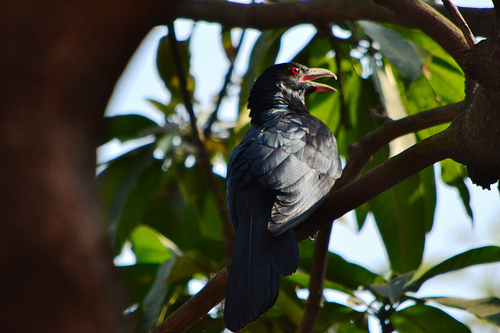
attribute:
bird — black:
[206, 50, 388, 287]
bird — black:
[194, 38, 394, 294]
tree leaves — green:
[403, 245, 499, 290]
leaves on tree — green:
[354, 207, 500, 332]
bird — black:
[223, 62, 340, 332]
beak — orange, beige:
[307, 69, 339, 83]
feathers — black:
[224, 219, 299, 333]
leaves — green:
[324, 196, 499, 333]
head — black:
[248, 63, 338, 111]